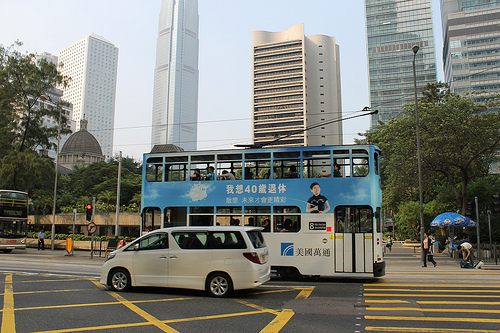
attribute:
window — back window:
[252, 230, 262, 244]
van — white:
[102, 229, 297, 299]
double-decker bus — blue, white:
[137, 144, 389, 280]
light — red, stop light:
[82, 198, 94, 224]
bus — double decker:
[132, 143, 382, 279]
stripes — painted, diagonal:
[47, 274, 499, 331]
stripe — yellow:
[362, 282, 499, 287]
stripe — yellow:
[363, 292, 499, 298]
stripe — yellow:
[365, 307, 499, 314]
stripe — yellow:
[364, 314, 499, 323]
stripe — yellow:
[364, 326, 499, 331]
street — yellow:
[1, 270, 499, 330]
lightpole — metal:
[404, 46, 431, 266]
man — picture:
[304, 180, 333, 213]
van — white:
[85, 224, 285, 311]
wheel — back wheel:
[207, 273, 234, 299]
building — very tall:
[240, 22, 349, 164]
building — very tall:
[139, 2, 204, 172]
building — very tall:
[52, 26, 122, 165]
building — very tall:
[358, 2, 447, 128]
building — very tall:
[429, 1, 496, 148]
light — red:
[78, 197, 95, 220]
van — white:
[97, 212, 281, 296]